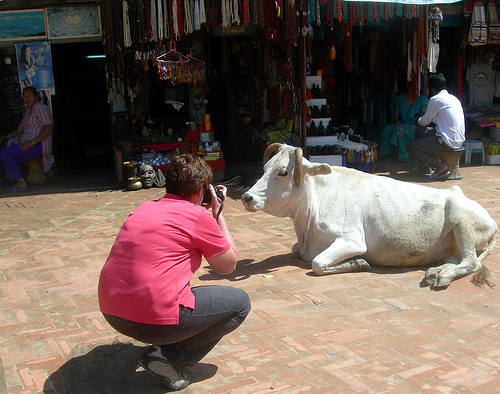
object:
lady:
[0, 87, 54, 192]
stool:
[22, 159, 47, 186]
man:
[95, 152, 251, 387]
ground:
[361, 160, 381, 172]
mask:
[139, 164, 156, 189]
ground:
[9, 189, 113, 242]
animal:
[240, 143, 496, 290]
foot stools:
[461, 138, 485, 166]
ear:
[305, 162, 333, 177]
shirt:
[10, 100, 56, 171]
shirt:
[96, 191, 233, 327]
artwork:
[13, 37, 58, 97]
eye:
[277, 170, 292, 178]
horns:
[263, 140, 283, 163]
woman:
[376, 80, 428, 158]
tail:
[464, 229, 496, 288]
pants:
[103, 283, 252, 374]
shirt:
[417, 90, 468, 150]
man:
[404, 72, 467, 173]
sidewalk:
[0, 154, 499, 392]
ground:
[255, 152, 496, 304]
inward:
[264, 141, 305, 186]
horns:
[293, 145, 304, 188]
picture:
[23, 148, 419, 318]